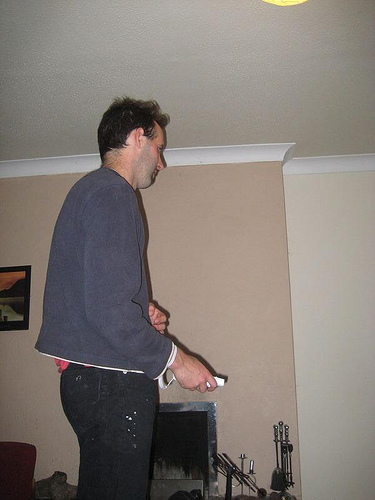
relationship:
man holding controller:
[67, 101, 192, 424] [203, 354, 235, 412]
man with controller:
[67, 101, 192, 424] [203, 354, 235, 412]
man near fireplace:
[67, 101, 192, 424] [166, 400, 228, 488]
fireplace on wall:
[166, 400, 228, 488] [184, 180, 280, 301]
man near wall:
[67, 101, 192, 424] [184, 180, 280, 301]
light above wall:
[260, 3, 324, 16] [184, 180, 280, 301]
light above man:
[260, 3, 324, 16] [67, 101, 192, 424]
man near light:
[67, 101, 192, 424] [260, 3, 324, 16]